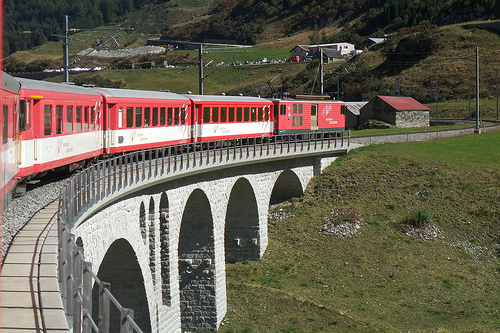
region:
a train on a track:
[4, 20, 389, 207]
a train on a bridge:
[12, 47, 474, 229]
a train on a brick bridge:
[8, 50, 347, 331]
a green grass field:
[326, 150, 498, 292]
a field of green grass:
[340, 177, 495, 309]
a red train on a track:
[22, 45, 389, 217]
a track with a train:
[19, 34, 376, 212]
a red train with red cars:
[23, 30, 412, 185]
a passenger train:
[15, 30, 382, 178]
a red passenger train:
[47, 43, 385, 194]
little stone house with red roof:
[351, 87, 441, 131]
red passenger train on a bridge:
[8, 70, 353, 163]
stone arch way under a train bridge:
[169, 185, 239, 327]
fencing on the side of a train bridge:
[53, 217, 118, 307]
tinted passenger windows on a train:
[109, 101, 192, 133]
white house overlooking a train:
[281, 31, 361, 69]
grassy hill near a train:
[327, 167, 465, 320]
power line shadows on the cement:
[8, 241, 49, 325]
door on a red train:
[308, 100, 320, 127]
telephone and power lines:
[67, 13, 279, 70]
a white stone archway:
[220, 173, 260, 310]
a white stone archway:
[262, 167, 303, 237]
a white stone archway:
[170, 183, 216, 329]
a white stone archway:
[80, 230, 161, 330]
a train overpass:
[0, 117, 365, 322]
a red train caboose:
[270, 91, 345, 136]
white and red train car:
[190, 87, 272, 142]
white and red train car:
[97, 81, 190, 151]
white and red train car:
[10, 74, 103, 183]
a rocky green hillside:
[255, 141, 498, 330]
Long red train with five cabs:
[1, 64, 353, 156]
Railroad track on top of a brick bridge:
[0, 126, 376, 331]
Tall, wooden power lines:
[310, 40, 488, 134]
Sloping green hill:
[272, 140, 497, 322]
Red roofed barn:
[357, 89, 432, 129]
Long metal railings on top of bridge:
[42, 127, 362, 331]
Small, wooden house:
[287, 39, 365, 62]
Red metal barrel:
[290, 52, 302, 62]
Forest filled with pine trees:
[0, 4, 140, 55]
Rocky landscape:
[320, 201, 499, 283]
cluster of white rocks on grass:
[314, 191, 371, 242]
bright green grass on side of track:
[420, 134, 482, 157]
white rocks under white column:
[230, 231, 277, 253]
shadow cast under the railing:
[145, 161, 339, 185]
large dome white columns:
[167, 178, 235, 325]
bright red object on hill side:
[276, 45, 303, 70]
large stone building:
[368, 85, 431, 124]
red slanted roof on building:
[361, 83, 452, 118]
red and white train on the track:
[43, 72, 343, 149]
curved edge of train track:
[8, 98, 383, 197]